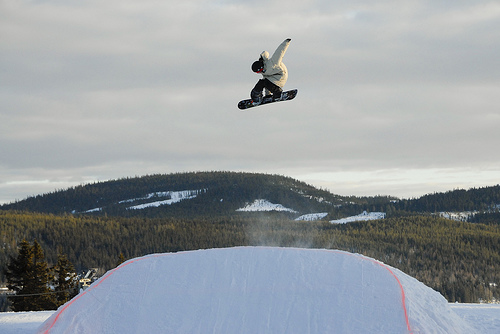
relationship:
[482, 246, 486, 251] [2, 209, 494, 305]
leaf on plant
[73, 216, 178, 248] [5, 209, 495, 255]
leaf part of plant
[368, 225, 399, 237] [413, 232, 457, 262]
leaf on a plant